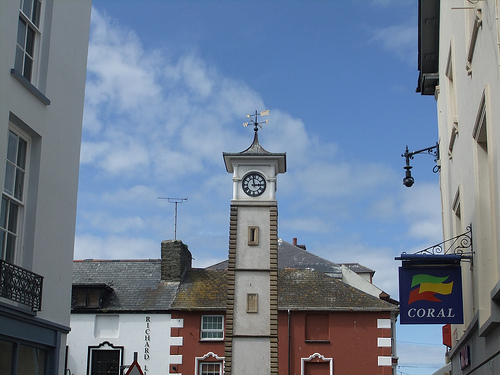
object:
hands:
[252, 173, 255, 187]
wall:
[0, 0, 93, 375]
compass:
[241, 108, 272, 130]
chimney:
[159, 239, 192, 281]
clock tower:
[222, 108, 287, 375]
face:
[241, 170, 266, 197]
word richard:
[144, 315, 152, 361]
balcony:
[0, 257, 46, 318]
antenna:
[156, 194, 191, 242]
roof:
[165, 265, 401, 314]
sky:
[71, 0, 450, 375]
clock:
[241, 170, 266, 197]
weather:
[72, 0, 451, 375]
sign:
[397, 264, 466, 327]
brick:
[375, 318, 392, 329]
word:
[406, 307, 455, 318]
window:
[12, 165, 25, 204]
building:
[0, 0, 94, 375]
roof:
[70, 258, 192, 313]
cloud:
[364, 0, 421, 73]